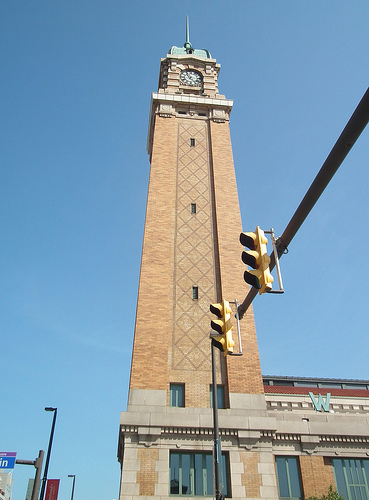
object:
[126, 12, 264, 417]
tower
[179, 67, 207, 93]
clock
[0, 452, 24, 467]
sign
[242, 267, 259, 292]
light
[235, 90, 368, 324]
pole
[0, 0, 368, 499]
sky